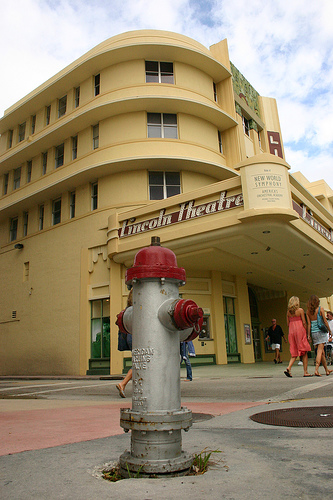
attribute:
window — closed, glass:
[144, 167, 186, 199]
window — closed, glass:
[143, 108, 180, 139]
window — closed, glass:
[141, 56, 179, 85]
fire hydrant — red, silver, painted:
[115, 236, 203, 477]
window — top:
[142, 57, 177, 85]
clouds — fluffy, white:
[222, 7, 325, 86]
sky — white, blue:
[3, 0, 332, 187]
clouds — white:
[21, 13, 80, 48]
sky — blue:
[229, 7, 329, 150]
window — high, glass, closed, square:
[70, 134, 78, 159]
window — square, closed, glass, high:
[68, 185, 75, 220]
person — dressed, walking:
[180, 337, 200, 386]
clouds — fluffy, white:
[260, 22, 295, 46]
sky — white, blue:
[196, 3, 209, 18]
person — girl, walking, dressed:
[300, 291, 331, 380]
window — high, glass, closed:
[133, 54, 189, 96]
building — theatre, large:
[15, 20, 308, 385]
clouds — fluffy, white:
[0, 0, 332, 188]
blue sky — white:
[0, 0, 331, 189]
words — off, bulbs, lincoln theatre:
[115, 188, 247, 239]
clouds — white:
[1, 1, 328, 57]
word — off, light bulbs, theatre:
[173, 192, 241, 216]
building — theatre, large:
[9, 30, 332, 364]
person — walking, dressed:
[296, 294, 331, 378]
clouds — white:
[233, 2, 331, 70]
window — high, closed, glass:
[147, 57, 174, 84]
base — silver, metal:
[97, 417, 224, 483]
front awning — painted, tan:
[107, 152, 332, 302]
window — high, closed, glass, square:
[88, 121, 102, 150]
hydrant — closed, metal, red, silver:
[103, 234, 221, 483]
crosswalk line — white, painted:
[258, 376, 332, 401]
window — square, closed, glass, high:
[87, 68, 105, 97]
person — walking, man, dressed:
[267, 318, 287, 364]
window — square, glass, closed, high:
[72, 85, 81, 108]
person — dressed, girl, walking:
[281, 290, 314, 379]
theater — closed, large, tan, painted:
[14, 34, 316, 380]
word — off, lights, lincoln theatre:
[114, 188, 247, 237]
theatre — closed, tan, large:
[5, 27, 322, 372]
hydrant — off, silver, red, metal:
[111, 230, 209, 473]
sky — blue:
[255, 20, 325, 80]